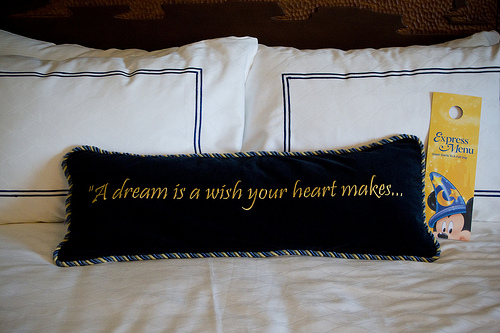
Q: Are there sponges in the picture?
A: No, there are no sponges.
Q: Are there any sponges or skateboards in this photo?
A: No, there are no sponges or skateboards.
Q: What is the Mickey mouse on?
A: The Mickey mouse is on the bag.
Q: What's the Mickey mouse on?
A: The Mickey mouse is on the bag.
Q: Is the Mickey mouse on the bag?
A: Yes, the Mickey mouse is on the bag.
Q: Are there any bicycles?
A: No, there are no bicycles.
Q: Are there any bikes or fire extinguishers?
A: No, there are no bikes or fire extinguishers.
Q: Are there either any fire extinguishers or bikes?
A: No, there are no bikes or fire extinguishers.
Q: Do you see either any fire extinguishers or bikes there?
A: No, there are no bikes or fire extinguishers.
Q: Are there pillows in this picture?
A: Yes, there is a pillow.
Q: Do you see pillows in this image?
A: Yes, there is a pillow.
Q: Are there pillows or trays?
A: Yes, there is a pillow.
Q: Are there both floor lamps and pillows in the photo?
A: No, there is a pillow but no floor lamps.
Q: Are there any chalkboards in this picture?
A: No, there are no chalkboards.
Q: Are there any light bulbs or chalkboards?
A: No, there are no chalkboards or light bulbs.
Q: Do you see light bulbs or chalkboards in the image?
A: No, there are no chalkboards or light bulbs.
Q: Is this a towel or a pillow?
A: This is a pillow.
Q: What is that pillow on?
A: The pillow is on the bed.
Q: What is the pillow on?
A: The pillow is on the bed.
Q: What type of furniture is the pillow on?
A: The pillow is on the bed.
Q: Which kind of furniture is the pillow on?
A: The pillow is on the bed.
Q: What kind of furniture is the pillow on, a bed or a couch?
A: The pillow is on a bed.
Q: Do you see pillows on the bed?
A: Yes, there is a pillow on the bed.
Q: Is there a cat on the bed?
A: No, there is a pillow on the bed.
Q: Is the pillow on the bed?
A: Yes, the pillow is on the bed.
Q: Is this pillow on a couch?
A: No, the pillow is on the bed.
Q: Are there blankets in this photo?
A: Yes, there is a blanket.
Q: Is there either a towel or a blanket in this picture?
A: Yes, there is a blanket.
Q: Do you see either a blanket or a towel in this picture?
A: Yes, there is a blanket.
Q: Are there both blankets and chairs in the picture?
A: No, there is a blanket but no chairs.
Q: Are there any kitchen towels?
A: No, there are no kitchen towels.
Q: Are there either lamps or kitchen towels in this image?
A: No, there are no kitchen towels or lamps.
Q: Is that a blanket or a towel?
A: That is a blanket.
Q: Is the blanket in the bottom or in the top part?
A: The blanket is in the bottom of the image.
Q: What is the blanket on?
A: The blanket is on the bed.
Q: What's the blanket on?
A: The blanket is on the bed.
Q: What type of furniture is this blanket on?
A: The blanket is on the bed.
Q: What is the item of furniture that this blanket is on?
A: The piece of furniture is a bed.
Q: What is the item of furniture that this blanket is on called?
A: The piece of furniture is a bed.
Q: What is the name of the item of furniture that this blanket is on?
A: The piece of furniture is a bed.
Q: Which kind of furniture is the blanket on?
A: The blanket is on the bed.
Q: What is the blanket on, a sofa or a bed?
A: The blanket is on a bed.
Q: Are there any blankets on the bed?
A: Yes, there is a blanket on the bed.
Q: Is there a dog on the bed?
A: No, there is a blanket on the bed.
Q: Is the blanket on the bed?
A: Yes, the blanket is on the bed.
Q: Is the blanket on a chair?
A: No, the blanket is on the bed.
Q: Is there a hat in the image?
A: Yes, there is a hat.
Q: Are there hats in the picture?
A: Yes, there is a hat.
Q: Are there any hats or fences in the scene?
A: Yes, there is a hat.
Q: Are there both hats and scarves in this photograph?
A: No, there is a hat but no scarves.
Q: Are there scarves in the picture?
A: No, there are no scarves.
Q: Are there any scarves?
A: No, there are no scarves.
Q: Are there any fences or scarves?
A: No, there are no scarves or fences.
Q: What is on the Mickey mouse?
A: The hat is on the Mickey mouse.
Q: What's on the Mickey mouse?
A: The hat is on the Mickey mouse.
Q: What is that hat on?
A: The hat is on the Mickey mouse.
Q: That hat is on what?
A: The hat is on the Mickey mouse.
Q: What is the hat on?
A: The hat is on the Mickey mouse.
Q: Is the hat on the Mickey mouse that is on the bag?
A: Yes, the hat is on the Mickey mouse.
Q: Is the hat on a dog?
A: No, the hat is on the Mickey mouse.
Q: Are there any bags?
A: Yes, there is a bag.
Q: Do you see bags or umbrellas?
A: Yes, there is a bag.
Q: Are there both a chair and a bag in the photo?
A: No, there is a bag but no chairs.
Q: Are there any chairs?
A: No, there are no chairs.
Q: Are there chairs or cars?
A: No, there are no chairs or cars.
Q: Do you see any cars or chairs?
A: No, there are no chairs or cars.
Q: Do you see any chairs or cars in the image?
A: No, there are no chairs or cars.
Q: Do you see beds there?
A: Yes, there is a bed.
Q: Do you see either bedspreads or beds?
A: Yes, there is a bed.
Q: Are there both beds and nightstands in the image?
A: No, there is a bed but no nightstands.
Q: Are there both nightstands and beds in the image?
A: No, there is a bed but no nightstands.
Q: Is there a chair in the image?
A: No, there are no chairs.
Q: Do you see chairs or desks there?
A: No, there are no chairs or desks.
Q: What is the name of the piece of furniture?
A: The piece of furniture is a bed.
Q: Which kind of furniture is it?
A: The piece of furniture is a bed.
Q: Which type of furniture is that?
A: That is a bed.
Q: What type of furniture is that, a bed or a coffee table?
A: That is a bed.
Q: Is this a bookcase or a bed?
A: This is a bed.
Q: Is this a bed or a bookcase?
A: This is a bed.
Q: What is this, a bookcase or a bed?
A: This is a bed.